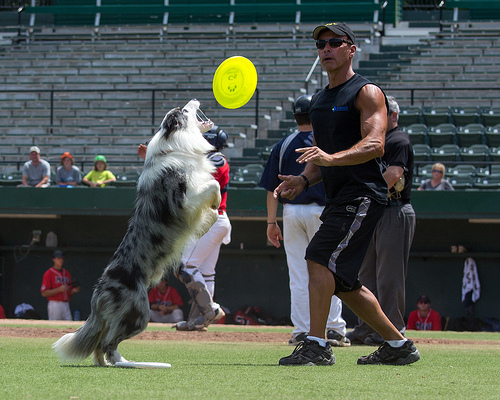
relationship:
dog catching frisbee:
[53, 95, 222, 367] [212, 56, 258, 109]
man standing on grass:
[273, 19, 420, 366] [0, 317, 499, 399]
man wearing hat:
[273, 19, 420, 366] [313, 22, 354, 46]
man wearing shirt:
[273, 19, 420, 366] [304, 72, 391, 205]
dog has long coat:
[53, 95, 222, 367] [52, 96, 217, 363]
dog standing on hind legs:
[53, 95, 222, 367] [91, 281, 150, 368]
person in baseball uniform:
[263, 94, 349, 347] [262, 129, 348, 335]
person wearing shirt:
[83, 151, 115, 187] [84, 170, 116, 185]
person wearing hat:
[56, 152, 82, 188] [59, 150, 73, 160]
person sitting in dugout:
[405, 290, 441, 329] [0, 185, 499, 331]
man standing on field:
[273, 19, 420, 366] [1, 318, 500, 400]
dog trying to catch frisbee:
[53, 95, 222, 367] [212, 56, 258, 109]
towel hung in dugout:
[460, 256, 482, 302] [0, 185, 499, 331]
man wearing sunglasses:
[273, 19, 420, 366] [316, 38, 352, 48]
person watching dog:
[83, 151, 115, 187] [53, 95, 222, 367]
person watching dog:
[56, 152, 82, 188] [53, 95, 222, 367]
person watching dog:
[17, 146, 50, 188] [53, 95, 222, 367]